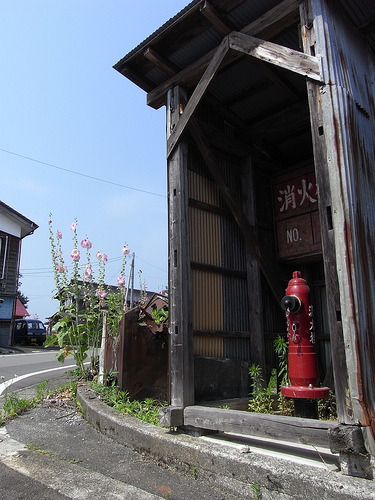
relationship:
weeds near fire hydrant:
[249, 328, 286, 412] [280, 271, 329, 420]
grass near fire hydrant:
[86, 366, 166, 427] [280, 271, 329, 420]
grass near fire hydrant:
[0, 378, 72, 424] [280, 271, 329, 420]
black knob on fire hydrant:
[281, 295, 301, 313] [279, 270, 331, 417]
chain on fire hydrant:
[282, 308, 297, 341] [279, 270, 331, 417]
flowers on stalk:
[45, 211, 147, 309] [116, 240, 127, 323]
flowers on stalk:
[45, 211, 147, 309] [80, 273, 90, 342]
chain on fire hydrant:
[286, 307, 297, 342] [277, 267, 328, 420]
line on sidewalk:
[1, 429, 163, 498] [87, 390, 351, 494]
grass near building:
[86, 379, 161, 424] [112, 1, 372, 478]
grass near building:
[0, 385, 51, 427] [112, 1, 372, 478]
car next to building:
[13, 319, 46, 346] [134, 0, 368, 466]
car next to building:
[11, 317, 46, 344] [0, 198, 39, 346]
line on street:
[0, 359, 93, 393] [6, 349, 52, 392]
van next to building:
[9, 306, 46, 356] [0, 194, 39, 348]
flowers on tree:
[48, 213, 148, 309] [45, 210, 122, 380]